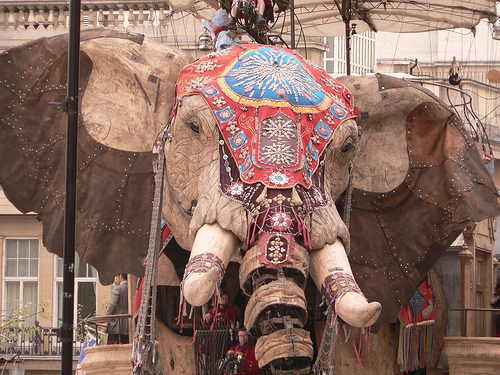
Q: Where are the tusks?
A: On the elephant.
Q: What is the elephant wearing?
A: A headdress.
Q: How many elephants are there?
A: One.